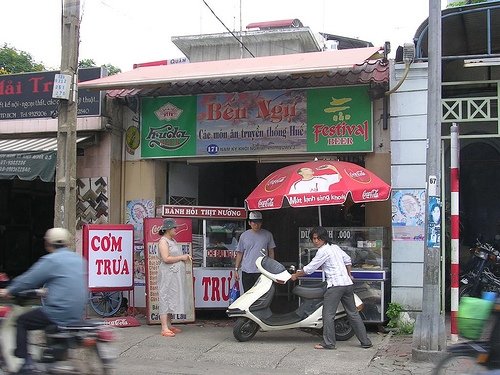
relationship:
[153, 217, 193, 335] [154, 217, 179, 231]
lady wearing a hat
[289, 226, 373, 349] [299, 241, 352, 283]
man in a shirt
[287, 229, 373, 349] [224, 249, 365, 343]
man has a bike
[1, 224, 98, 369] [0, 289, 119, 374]
man riding scooter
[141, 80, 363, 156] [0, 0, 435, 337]
advertisements for restuarant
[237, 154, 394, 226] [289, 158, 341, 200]
umbrella with ads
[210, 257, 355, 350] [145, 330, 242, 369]
bike parked on pavement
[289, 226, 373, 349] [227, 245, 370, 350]
man standing in front of moped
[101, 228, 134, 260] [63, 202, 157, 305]
letter m on sign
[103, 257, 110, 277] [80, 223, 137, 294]
letter r on sign